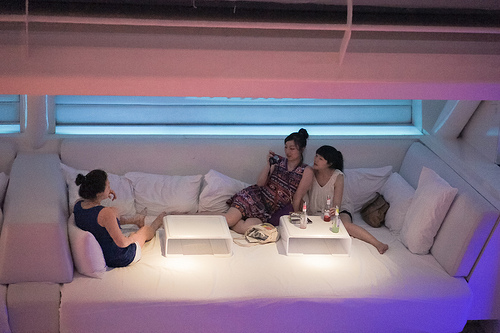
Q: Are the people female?
A: Yes, all the people are female.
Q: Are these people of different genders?
A: No, all the people are female.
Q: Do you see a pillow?
A: Yes, there is a pillow.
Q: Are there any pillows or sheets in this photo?
A: Yes, there is a pillow.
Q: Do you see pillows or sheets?
A: Yes, there is a pillow.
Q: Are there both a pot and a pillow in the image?
A: No, there is a pillow but no pots.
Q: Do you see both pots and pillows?
A: No, there is a pillow but no pots.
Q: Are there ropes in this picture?
A: No, there are no ropes.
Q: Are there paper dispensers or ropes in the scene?
A: No, there are no ropes or paper dispensers.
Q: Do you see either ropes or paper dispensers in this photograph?
A: No, there are no ropes or paper dispensers.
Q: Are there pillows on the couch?
A: Yes, there is a pillow on the couch.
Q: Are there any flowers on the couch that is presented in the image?
A: No, there is a pillow on the couch.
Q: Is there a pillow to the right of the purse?
A: Yes, there is a pillow to the right of the purse.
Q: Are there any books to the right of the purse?
A: No, there is a pillow to the right of the purse.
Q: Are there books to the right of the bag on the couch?
A: No, there is a pillow to the right of the purse.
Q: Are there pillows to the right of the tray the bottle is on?
A: Yes, there is a pillow to the right of the tray.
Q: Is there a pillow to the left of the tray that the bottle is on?
A: No, the pillow is to the right of the tray.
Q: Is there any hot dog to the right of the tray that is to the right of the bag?
A: No, there is a pillow to the right of the tray.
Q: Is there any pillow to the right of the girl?
A: Yes, there is a pillow to the right of the girl.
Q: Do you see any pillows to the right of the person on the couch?
A: Yes, there is a pillow to the right of the girl.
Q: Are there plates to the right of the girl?
A: No, there is a pillow to the right of the girl.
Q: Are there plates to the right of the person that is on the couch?
A: No, there is a pillow to the right of the girl.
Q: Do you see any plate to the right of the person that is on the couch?
A: No, there is a pillow to the right of the girl.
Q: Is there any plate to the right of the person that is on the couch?
A: No, there is a pillow to the right of the girl.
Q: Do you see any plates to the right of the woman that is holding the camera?
A: No, there is a pillow to the right of the woman.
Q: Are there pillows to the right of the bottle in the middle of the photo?
A: Yes, there is a pillow to the right of the bottle.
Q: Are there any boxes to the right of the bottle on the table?
A: No, there is a pillow to the right of the bottle.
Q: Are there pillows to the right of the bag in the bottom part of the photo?
A: Yes, there is a pillow to the right of the bag.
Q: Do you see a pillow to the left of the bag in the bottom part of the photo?
A: No, the pillow is to the right of the bag.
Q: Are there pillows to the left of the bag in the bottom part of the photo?
A: No, the pillow is to the right of the bag.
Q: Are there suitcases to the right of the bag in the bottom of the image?
A: No, there is a pillow to the right of the bag.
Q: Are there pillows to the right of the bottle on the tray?
A: Yes, there is a pillow to the right of the bottle.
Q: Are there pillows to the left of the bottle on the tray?
A: No, the pillow is to the right of the bottle.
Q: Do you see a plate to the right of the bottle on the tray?
A: No, there is a pillow to the right of the bottle.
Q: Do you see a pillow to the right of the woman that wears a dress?
A: Yes, there is a pillow to the right of the woman.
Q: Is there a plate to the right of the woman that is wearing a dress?
A: No, there is a pillow to the right of the woman.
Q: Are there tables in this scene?
A: Yes, there is a table.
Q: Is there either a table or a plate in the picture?
A: Yes, there is a table.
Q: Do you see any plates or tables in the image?
A: Yes, there is a table.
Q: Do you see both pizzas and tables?
A: No, there is a table but no pizzas.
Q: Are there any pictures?
A: No, there are no pictures.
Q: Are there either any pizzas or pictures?
A: No, there are no pictures or pizzas.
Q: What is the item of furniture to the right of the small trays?
A: The piece of furniture is a table.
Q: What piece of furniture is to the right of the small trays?
A: The piece of furniture is a table.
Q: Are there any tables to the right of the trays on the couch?
A: Yes, there is a table to the right of the trays.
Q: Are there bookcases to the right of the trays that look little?
A: No, there is a table to the right of the trays.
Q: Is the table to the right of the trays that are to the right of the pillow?
A: Yes, the table is to the right of the trays.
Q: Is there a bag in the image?
A: Yes, there is a bag.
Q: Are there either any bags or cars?
A: Yes, there is a bag.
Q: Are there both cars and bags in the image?
A: No, there is a bag but no cars.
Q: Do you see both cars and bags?
A: No, there is a bag but no cars.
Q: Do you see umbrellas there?
A: No, there are no umbrellas.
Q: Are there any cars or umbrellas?
A: No, there are no umbrellas or cars.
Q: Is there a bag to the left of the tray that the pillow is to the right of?
A: Yes, there is a bag to the left of the tray.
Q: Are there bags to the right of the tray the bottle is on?
A: No, the bag is to the left of the tray.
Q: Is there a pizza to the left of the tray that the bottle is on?
A: No, there is a bag to the left of the tray.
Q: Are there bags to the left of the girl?
A: Yes, there is a bag to the left of the girl.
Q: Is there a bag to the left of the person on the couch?
A: Yes, there is a bag to the left of the girl.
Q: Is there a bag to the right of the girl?
A: No, the bag is to the left of the girl.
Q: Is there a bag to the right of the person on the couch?
A: No, the bag is to the left of the girl.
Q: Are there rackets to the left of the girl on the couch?
A: No, there is a bag to the left of the girl.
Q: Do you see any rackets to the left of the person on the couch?
A: No, there is a bag to the left of the girl.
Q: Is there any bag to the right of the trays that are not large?
A: Yes, there is a bag to the right of the trays.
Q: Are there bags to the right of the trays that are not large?
A: Yes, there is a bag to the right of the trays.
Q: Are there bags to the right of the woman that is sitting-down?
A: Yes, there is a bag to the right of the woman.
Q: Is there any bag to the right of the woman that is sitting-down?
A: Yes, there is a bag to the right of the woman.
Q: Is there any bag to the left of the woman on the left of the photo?
A: No, the bag is to the right of the woman.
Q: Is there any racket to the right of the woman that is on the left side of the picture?
A: No, there is a bag to the right of the woman.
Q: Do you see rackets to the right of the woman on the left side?
A: No, there is a bag to the right of the woman.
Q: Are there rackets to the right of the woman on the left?
A: No, there is a bag to the right of the woman.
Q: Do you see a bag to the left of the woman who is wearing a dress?
A: Yes, there is a bag to the left of the woman.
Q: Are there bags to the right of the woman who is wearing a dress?
A: No, the bag is to the left of the woman.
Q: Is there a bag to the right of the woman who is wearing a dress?
A: No, the bag is to the left of the woman.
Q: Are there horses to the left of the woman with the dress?
A: No, there is a bag to the left of the woman.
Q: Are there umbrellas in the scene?
A: No, there are no umbrellas.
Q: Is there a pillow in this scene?
A: Yes, there is a pillow.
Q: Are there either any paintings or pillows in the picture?
A: Yes, there is a pillow.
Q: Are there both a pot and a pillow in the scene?
A: No, there is a pillow but no pots.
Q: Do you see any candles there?
A: No, there are no candles.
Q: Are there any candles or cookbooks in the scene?
A: No, there are no candles or cookbooks.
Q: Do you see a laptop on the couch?
A: No, there is a pillow on the couch.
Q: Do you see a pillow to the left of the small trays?
A: Yes, there is a pillow to the left of the trays.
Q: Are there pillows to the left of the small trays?
A: Yes, there is a pillow to the left of the trays.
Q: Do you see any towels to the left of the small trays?
A: No, there is a pillow to the left of the trays.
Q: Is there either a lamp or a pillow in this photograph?
A: Yes, there is a pillow.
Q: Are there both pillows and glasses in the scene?
A: No, there is a pillow but no glasses.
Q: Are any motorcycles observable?
A: No, there are no motorcycles.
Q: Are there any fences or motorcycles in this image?
A: No, there are no motorcycles or fences.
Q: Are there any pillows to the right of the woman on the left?
A: Yes, there is a pillow to the right of the woman.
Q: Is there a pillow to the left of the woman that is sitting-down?
A: No, the pillow is to the right of the woman.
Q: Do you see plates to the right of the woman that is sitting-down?
A: No, there is a pillow to the right of the woman.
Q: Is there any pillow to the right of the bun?
A: Yes, there is a pillow to the right of the bun.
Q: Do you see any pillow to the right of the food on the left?
A: Yes, there is a pillow to the right of the bun.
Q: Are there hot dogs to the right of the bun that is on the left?
A: No, there is a pillow to the right of the bun.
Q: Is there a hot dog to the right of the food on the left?
A: No, there is a pillow to the right of the bun.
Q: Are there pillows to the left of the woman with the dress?
A: Yes, there is a pillow to the left of the woman.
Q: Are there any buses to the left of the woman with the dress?
A: No, there is a pillow to the left of the woman.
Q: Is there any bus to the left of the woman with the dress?
A: No, there is a pillow to the left of the woman.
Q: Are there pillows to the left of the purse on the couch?
A: Yes, there is a pillow to the left of the purse.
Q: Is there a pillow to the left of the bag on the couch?
A: Yes, there is a pillow to the left of the purse.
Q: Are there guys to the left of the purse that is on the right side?
A: No, there is a pillow to the left of the purse.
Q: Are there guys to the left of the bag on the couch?
A: No, there is a pillow to the left of the purse.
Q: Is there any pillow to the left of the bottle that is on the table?
A: Yes, there is a pillow to the left of the bottle.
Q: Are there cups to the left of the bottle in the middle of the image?
A: No, there is a pillow to the left of the bottle.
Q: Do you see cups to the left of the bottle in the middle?
A: No, there is a pillow to the left of the bottle.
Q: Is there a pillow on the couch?
A: Yes, there is a pillow on the couch.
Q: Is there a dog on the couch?
A: No, there is a pillow on the couch.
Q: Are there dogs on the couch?
A: No, there is a pillow on the couch.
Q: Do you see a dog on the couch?
A: No, there is a pillow on the couch.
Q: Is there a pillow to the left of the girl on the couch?
A: Yes, there is a pillow to the left of the girl.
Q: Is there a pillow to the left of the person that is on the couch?
A: Yes, there is a pillow to the left of the girl.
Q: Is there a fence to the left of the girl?
A: No, there is a pillow to the left of the girl.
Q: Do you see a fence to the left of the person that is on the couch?
A: No, there is a pillow to the left of the girl.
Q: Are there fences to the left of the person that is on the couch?
A: No, there is a pillow to the left of the girl.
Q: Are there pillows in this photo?
A: Yes, there is a pillow.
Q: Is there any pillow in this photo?
A: Yes, there is a pillow.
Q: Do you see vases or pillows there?
A: Yes, there is a pillow.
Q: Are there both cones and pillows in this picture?
A: No, there is a pillow but no cones.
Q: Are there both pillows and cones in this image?
A: No, there is a pillow but no cones.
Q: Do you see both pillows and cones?
A: No, there is a pillow but no cones.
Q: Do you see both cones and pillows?
A: No, there is a pillow but no cones.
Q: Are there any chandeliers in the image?
A: No, there are no chandeliers.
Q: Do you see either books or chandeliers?
A: No, there are no chandeliers or books.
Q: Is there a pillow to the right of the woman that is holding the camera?
A: Yes, there is a pillow to the right of the woman.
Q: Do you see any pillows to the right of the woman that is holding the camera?
A: Yes, there is a pillow to the right of the woman.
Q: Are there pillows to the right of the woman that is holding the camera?
A: Yes, there is a pillow to the right of the woman.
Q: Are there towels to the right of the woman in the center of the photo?
A: No, there is a pillow to the right of the woman.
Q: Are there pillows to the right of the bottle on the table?
A: Yes, there is a pillow to the right of the bottle.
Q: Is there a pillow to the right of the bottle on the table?
A: Yes, there is a pillow to the right of the bottle.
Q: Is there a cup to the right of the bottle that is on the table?
A: No, there is a pillow to the right of the bottle.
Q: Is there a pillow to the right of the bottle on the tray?
A: Yes, there is a pillow to the right of the bottle.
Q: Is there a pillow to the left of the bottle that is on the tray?
A: No, the pillow is to the right of the bottle.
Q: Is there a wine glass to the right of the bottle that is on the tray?
A: No, there is a pillow to the right of the bottle.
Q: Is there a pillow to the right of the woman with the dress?
A: Yes, there is a pillow to the right of the woman.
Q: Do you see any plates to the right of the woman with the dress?
A: No, there is a pillow to the right of the woman.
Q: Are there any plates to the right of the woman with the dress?
A: No, there is a pillow to the right of the woman.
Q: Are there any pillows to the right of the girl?
A: Yes, there is a pillow to the right of the girl.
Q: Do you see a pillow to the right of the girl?
A: Yes, there is a pillow to the right of the girl.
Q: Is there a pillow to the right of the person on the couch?
A: Yes, there is a pillow to the right of the girl.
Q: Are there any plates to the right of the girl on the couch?
A: No, there is a pillow to the right of the girl.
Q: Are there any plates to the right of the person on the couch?
A: No, there is a pillow to the right of the girl.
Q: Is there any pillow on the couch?
A: Yes, there is a pillow on the couch.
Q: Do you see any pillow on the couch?
A: Yes, there is a pillow on the couch.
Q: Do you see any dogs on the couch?
A: No, there is a pillow on the couch.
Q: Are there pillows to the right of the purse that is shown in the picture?
A: Yes, there is a pillow to the right of the purse.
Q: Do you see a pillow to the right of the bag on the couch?
A: Yes, there is a pillow to the right of the purse.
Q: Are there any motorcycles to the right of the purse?
A: No, there is a pillow to the right of the purse.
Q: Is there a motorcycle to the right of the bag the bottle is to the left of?
A: No, there is a pillow to the right of the purse.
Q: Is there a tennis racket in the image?
A: No, there are no rackets.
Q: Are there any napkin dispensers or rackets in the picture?
A: No, there are no rackets or napkin dispensers.